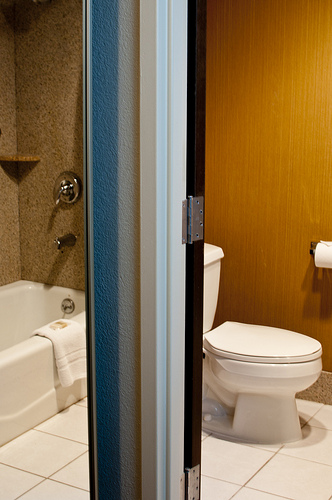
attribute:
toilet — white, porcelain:
[206, 247, 327, 446]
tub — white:
[5, 277, 85, 439]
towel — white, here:
[34, 317, 85, 407]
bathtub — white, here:
[4, 277, 81, 442]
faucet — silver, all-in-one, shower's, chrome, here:
[53, 230, 76, 255]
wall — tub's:
[15, 6, 85, 284]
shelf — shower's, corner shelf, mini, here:
[0, 150, 40, 168]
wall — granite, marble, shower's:
[4, 0, 81, 284]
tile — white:
[2, 391, 331, 497]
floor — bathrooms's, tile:
[2, 386, 331, 492]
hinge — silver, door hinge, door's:
[183, 193, 207, 247]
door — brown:
[182, 1, 209, 500]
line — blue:
[91, 6, 120, 496]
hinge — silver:
[183, 464, 200, 497]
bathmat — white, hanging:
[35, 317, 86, 390]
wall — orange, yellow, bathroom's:
[199, 1, 328, 408]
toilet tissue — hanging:
[313, 242, 331, 276]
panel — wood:
[202, 0, 329, 372]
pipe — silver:
[56, 231, 75, 252]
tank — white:
[203, 238, 225, 330]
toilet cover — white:
[209, 320, 324, 365]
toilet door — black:
[189, 0, 214, 496]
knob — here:
[50, 171, 82, 213]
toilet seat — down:
[208, 317, 324, 365]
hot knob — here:
[47, 167, 81, 217]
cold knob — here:
[47, 173, 81, 221]